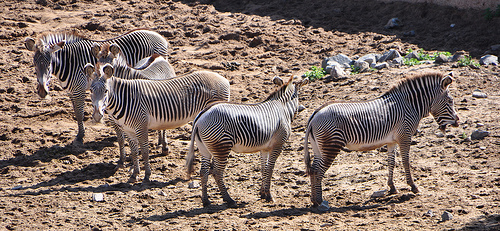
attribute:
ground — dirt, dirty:
[1, 1, 499, 228]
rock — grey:
[323, 50, 356, 83]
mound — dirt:
[245, 0, 492, 59]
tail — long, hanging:
[180, 125, 197, 178]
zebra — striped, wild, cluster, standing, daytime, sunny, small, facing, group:
[303, 68, 461, 211]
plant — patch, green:
[307, 65, 326, 82]